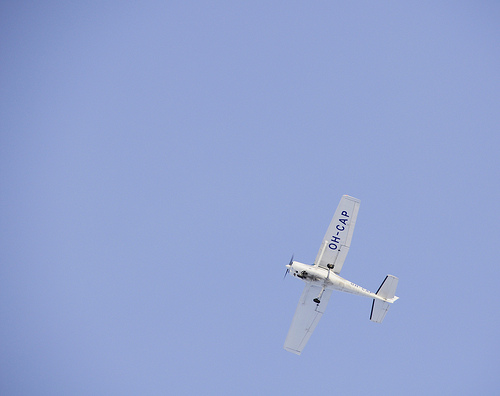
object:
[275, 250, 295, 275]
propellers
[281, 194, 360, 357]
wings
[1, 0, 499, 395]
blue sky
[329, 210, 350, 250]
oh-cap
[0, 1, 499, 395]
air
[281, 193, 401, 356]
plane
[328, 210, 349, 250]
letters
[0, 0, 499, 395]
clouds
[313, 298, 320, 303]
wheel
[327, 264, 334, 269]
wheel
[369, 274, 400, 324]
tail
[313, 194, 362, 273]
wing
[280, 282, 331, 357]
wing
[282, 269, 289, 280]
propeller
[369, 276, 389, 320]
stripe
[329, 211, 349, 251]
writing